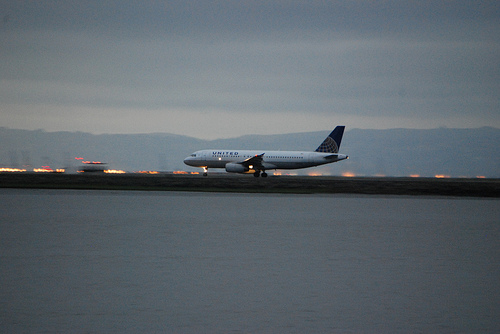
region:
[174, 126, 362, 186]
plane on the tarmac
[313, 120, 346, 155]
white and blue tail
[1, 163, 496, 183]
several small lights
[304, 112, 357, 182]
tail of the plane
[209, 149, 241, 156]
United logo on the side of the plane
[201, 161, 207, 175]
front wheel is down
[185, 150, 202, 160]
windows on the front of the plane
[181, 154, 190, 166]
nose of the plane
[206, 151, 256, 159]
windows on the side of the plane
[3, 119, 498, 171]
mountains in the distance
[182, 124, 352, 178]
An airplane preparing to land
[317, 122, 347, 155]
The plane's dark tail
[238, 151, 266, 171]
A dark wing on the plane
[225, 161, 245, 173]
A large white jet engine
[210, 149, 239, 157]
Black letters on the plane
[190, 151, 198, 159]
The cockpit windows on the plane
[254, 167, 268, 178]
The plane's rear wheels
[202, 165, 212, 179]
The plane's large front wheel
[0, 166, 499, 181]
A line of lights in the background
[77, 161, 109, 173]
A building in the distance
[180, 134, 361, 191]
a united airlines commercial plane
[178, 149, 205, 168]
the nose of a united airlines commercial plane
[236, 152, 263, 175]
the wing of a united airlines commercial plane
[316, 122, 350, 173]
the tail of a united airlines commercial plane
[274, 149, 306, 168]
the windows of a united airlines commercial plane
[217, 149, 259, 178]
the turbines of a united airlines commercial plane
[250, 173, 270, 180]
the wheels of a united airlines commercial plane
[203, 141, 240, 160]
the written logo of a united airlines commercial plane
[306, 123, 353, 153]
the main logo of a united airlines commercial plane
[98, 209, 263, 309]
a small lake with many ripples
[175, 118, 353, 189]
white airplane with blue tail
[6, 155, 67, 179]
bright lights of airport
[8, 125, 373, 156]
mountain range in background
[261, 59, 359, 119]
hazy clouds in the sky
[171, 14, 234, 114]
hazy clouds in the sky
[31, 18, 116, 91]
hazy clouds in the sky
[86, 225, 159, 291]
clear water near shore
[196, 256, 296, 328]
clear water near shore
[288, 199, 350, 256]
clear water near shore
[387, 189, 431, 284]
clear water near shore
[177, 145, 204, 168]
cockpit of a plane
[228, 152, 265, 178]
wing of a plane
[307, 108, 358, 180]
back wing of a plane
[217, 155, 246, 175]
turbine of a plane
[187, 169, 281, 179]
wheels of a plane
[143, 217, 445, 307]
a body of water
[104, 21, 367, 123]
sky full of clouds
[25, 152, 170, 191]
lights in the background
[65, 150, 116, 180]
a building on a field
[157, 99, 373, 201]
plane in mid air